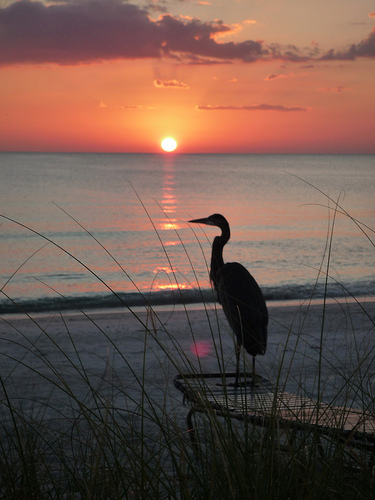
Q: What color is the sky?
A: Red.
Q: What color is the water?
A: Blue.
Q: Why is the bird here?
A: Watching the sunset.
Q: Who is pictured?
A: A bird.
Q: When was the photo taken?
A: Sunset.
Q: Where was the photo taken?
A: At a beach.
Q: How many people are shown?
A: Zero.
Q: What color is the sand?
A: Grey.